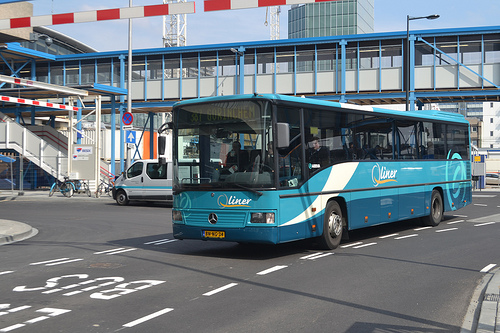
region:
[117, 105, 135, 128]
blue circle sign with red x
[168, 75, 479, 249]
blue bus carrying passengers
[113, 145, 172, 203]
white van parked on the street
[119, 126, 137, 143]
blue sign with white arrow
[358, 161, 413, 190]
word on the side of the bus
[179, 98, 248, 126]
number on the front of the bus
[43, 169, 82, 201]
blue bicycle by the pole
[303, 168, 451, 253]
tires on the bus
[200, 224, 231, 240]
yellow license plate on the bus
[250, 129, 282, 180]
driver is driving the bus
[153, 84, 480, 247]
a bus color blue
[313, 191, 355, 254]
front wheel of bus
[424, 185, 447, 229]
back wheel of bus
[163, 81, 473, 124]
roof of bus is blue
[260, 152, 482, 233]
a white stripe on side the bus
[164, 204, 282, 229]
headlights on front of bus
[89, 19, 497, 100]
a blue bridge on top the street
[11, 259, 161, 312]
the word BUS on road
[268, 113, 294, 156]
a mirror on side the bus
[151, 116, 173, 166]
a mirror on side the bus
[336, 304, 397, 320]
Part of the street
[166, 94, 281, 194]
A window on the bus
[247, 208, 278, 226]
The left headlight of the bus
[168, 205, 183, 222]
The right headlight of the bus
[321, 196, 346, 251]
The front tire of the bus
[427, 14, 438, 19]
Part of the street light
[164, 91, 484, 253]
A blue bus on the road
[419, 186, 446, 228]
The back tire of the bus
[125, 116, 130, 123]
Part of the sign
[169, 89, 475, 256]
the bus is blue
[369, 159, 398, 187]
white letters on bus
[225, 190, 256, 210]
white letters on bus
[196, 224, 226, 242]
yellow license plate on bus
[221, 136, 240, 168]
person sitting on the bus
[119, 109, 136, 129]
blue sign on pole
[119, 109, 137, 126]
red lines on sign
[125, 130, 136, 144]
white arrow on sign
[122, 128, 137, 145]
the sign is blue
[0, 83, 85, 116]
sign is red and white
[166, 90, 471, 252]
a blue bus on a road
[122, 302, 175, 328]
a white stripe painted in a road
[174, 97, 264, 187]
the front window of a bus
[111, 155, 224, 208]
a white van on the side of the road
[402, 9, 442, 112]
a lightpole behind a bus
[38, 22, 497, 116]
a blue walkway above a bus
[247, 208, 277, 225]
the headlight of a bus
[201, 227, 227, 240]
a yellow license plate on a bus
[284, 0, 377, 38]
a tall building behind an elevated walkway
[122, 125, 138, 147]
a blue sign with a white arrow